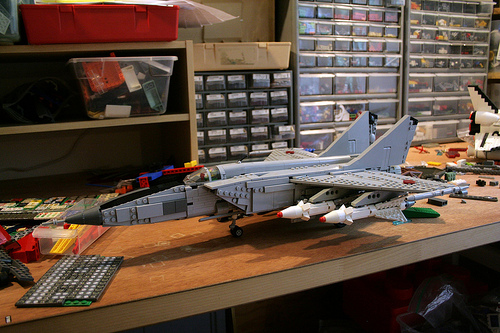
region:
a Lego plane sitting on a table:
[45, 106, 471, 239]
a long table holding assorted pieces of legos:
[7, 127, 499, 319]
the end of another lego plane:
[463, 82, 499, 160]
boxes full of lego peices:
[297, 1, 398, 154]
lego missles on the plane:
[272, 192, 405, 242]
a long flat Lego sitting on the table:
[17, 249, 119, 316]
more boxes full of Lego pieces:
[409, 1, 497, 134]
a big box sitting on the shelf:
[66, 52, 174, 122]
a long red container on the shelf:
[16, 2, 186, 47]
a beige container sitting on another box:
[191, 35, 294, 73]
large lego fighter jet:
[63, 108, 464, 243]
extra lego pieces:
[7, 192, 114, 311]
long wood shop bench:
[1, 153, 488, 327]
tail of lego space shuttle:
[457, 80, 498, 155]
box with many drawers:
[194, 68, 301, 158]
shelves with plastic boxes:
[301, 61, 488, 152]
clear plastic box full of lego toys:
[79, 53, 178, 116]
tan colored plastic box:
[191, 37, 307, 69]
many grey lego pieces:
[409, 135, 495, 227]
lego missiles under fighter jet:
[273, 185, 425, 250]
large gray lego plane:
[38, 104, 473, 268]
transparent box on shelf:
[59, 45, 199, 142]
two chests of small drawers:
[289, 2, 498, 117]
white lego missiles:
[263, 172, 403, 237]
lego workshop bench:
[19, 17, 456, 316]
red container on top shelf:
[2, 1, 196, 54]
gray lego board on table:
[12, 246, 130, 313]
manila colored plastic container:
[181, 34, 296, 74]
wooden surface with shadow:
[129, 232, 270, 270]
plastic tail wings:
[306, 88, 427, 180]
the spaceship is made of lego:
[38, 95, 484, 280]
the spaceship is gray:
[68, 56, 498, 281]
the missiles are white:
[259, 183, 481, 224]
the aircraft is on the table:
[34, 115, 499, 238]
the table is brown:
[144, 226, 286, 301]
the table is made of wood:
[141, 239, 241, 298]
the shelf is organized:
[292, 10, 472, 142]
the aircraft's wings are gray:
[247, 134, 469, 259]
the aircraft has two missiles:
[265, 190, 446, 250]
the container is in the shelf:
[72, 50, 179, 123]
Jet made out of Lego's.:
[40, 107, 469, 227]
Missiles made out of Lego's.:
[276, 186, 466, 227]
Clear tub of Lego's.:
[67, 51, 174, 116]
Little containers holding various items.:
[193, 70, 295, 167]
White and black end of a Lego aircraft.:
[466, 80, 498, 152]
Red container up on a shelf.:
[19, 0, 184, 39]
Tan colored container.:
[190, 37, 292, 71]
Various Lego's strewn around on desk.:
[417, 138, 472, 169]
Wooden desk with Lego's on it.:
[0, 138, 499, 331]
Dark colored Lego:
[0, 245, 37, 287]